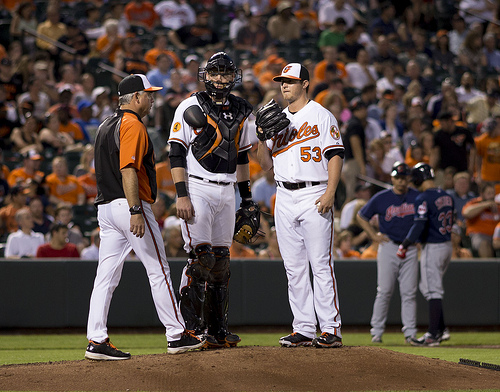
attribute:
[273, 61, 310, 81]
cap — orange, white, black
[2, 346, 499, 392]
mound — pitcher's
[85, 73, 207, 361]
man — standing, orioles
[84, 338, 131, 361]
shoe — tennis shoe, black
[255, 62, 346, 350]
man — standing, number 53, orioles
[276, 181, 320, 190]
belt — black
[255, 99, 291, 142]
glove — baseball glove, black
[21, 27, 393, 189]
pole — long, black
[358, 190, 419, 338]
uniform — gray, blue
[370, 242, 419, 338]
pants — gray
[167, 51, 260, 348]
player — standing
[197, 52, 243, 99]
face mask — black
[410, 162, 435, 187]
helmet — black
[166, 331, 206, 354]
shoe — black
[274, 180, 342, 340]
pants — white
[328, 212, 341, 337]
stripe — red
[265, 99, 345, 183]
shirt — white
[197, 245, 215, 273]
knee — protected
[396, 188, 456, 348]
uniform — blue, gray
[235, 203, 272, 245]
mitt — catcher's, leather, black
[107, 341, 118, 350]
shoelaces — orange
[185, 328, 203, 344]
shoelaces — orange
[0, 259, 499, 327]
fence — green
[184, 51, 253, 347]
gear — protective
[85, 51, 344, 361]
team — professional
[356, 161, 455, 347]
team — professional